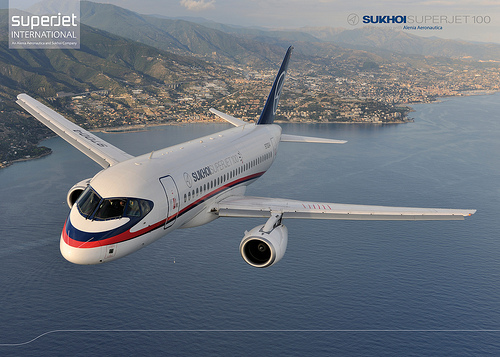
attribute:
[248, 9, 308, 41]
clouds — white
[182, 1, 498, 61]
clouds — white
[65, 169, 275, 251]
stripes — red and white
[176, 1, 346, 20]
clouds — white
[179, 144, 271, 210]
windows — row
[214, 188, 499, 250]
wing — large, side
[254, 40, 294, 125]
tail fin — blue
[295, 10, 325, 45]
sky — blue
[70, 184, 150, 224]
windows — airplane, pilot's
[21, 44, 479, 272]
airplane — white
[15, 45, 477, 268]
plane — white, water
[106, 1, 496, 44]
sky — white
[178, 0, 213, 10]
clouds — white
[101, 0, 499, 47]
sky — blue